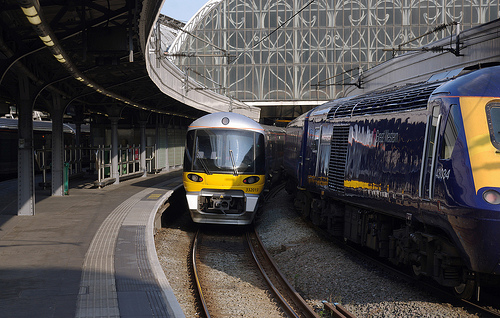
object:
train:
[177, 111, 305, 225]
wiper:
[226, 151, 240, 175]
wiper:
[199, 156, 211, 175]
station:
[3, 0, 261, 317]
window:
[347, 106, 430, 193]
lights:
[26, 14, 42, 26]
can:
[64, 159, 72, 196]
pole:
[52, 103, 66, 196]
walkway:
[33, 142, 156, 190]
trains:
[283, 62, 499, 301]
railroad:
[190, 228, 320, 317]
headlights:
[183, 173, 203, 183]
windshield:
[188, 131, 263, 171]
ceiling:
[3, 0, 208, 122]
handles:
[428, 113, 444, 201]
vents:
[334, 127, 346, 190]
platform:
[0, 169, 187, 317]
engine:
[184, 111, 269, 225]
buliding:
[164, 0, 499, 122]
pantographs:
[190, 228, 314, 317]